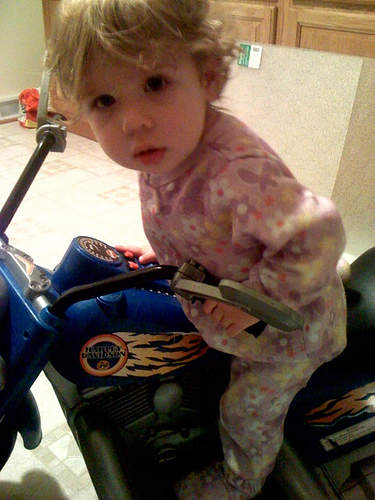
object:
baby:
[42, 2, 349, 499]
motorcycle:
[1, 67, 375, 496]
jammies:
[138, 108, 353, 500]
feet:
[178, 465, 257, 498]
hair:
[42, 0, 245, 129]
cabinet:
[275, 1, 375, 58]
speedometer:
[76, 232, 121, 269]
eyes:
[84, 91, 119, 113]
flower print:
[262, 207, 302, 246]